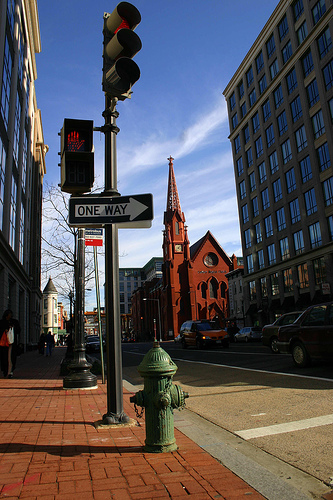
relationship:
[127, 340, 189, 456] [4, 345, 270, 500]
fire hydrant on sidewalk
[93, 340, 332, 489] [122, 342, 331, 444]
street has line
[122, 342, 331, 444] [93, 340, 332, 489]
line painted on street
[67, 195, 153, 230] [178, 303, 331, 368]
sign for traffic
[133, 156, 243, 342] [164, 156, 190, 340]
church has steeple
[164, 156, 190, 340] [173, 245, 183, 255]
steeple has a clock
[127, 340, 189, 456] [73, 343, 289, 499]
fire hydrant on roadside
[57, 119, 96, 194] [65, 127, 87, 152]
indicator has hand signal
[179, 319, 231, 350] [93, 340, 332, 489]
van in street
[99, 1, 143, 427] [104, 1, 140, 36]
traffic light has light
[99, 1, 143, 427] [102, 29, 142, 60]
traffic light has light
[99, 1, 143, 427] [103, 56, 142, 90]
traffic light has light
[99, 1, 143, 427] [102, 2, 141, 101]
traffic light has three lights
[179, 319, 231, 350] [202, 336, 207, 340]
van has turn signal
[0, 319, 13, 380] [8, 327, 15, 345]
woman holding bag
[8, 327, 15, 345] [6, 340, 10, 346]
bag in hand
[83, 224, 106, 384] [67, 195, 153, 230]
sign behind sign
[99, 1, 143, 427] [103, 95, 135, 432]
traffic light on a pole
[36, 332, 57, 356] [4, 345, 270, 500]
people are walking on sidewalk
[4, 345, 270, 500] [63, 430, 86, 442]
sidewalk paved brick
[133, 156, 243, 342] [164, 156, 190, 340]
church has a steeple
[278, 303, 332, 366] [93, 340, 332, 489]
car driving on street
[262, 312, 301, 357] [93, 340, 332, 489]
car driving on street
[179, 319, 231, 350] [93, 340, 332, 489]
car driving on street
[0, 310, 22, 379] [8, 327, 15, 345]
woman's holding bag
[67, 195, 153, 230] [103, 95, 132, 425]
sign on a pole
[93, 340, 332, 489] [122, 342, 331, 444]
lines has lines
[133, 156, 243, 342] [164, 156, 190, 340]
church has a tower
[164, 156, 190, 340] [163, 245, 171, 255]
tower has a clock